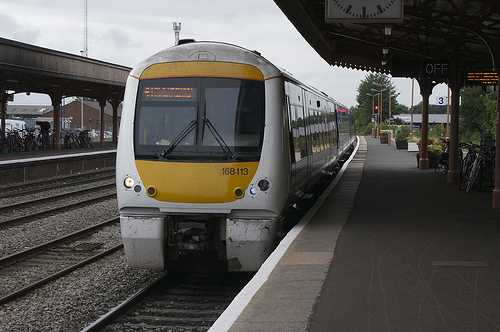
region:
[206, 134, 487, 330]
A platform near the train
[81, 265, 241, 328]
Train tracks below the train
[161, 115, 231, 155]
Windshield wipers on the train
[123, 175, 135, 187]
A headlight on the train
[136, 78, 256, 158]
A window on the front of the train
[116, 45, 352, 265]
A train on the tracks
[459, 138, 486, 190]
A bicycle on the platform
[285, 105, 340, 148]
Windows on the side of the train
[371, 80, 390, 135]
Lamp posts near the platform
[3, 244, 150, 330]
Gravel beside the train tracks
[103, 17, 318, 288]
the train is at the station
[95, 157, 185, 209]
the headlight is on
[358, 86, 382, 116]
the light is red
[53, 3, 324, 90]
the sky is overcast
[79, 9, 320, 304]
the train is yellow and grey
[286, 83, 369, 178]
the reflection in the window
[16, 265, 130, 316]
the gravel is grey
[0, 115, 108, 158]
bikes parked on the platform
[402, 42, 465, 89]
the sign says off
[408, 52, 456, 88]
the letters are white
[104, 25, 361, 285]
a train is at the platform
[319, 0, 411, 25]
a railway platform clock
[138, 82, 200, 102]
destination displayed on front of a train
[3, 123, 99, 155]
bicycles parked on a railway platform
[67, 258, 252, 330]
metal railway track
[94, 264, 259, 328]
wooden sleepers between railway tracks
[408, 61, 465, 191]
pillars on a railway platform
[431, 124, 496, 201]
bicycles on a railway platform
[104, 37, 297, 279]
yellow black and grey front of a train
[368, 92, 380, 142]
red traffic light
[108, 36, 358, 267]
A yellow and white train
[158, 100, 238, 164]
A pair of windshield wipers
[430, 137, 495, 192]
A row of bicycles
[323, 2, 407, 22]
an overhanging clock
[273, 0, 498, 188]
A large canopy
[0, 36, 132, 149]
A large canopy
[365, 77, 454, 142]
A row of tall street lights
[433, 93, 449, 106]
A sign with the number 3 on it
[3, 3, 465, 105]
A grey cloudy sky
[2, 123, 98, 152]
A line of bicycles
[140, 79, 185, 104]
the marquee on a train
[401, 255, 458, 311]
scratches on the platform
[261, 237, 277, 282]
a white line on the edge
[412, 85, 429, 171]
a tan support column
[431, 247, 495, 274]
a rectangle on the platform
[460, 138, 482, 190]
bikes leaning against a rack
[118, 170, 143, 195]
a lit headlight on the train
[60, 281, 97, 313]
gray gravel between the tracks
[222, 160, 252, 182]
black numbers on the train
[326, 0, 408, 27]
a clock on the ceiling